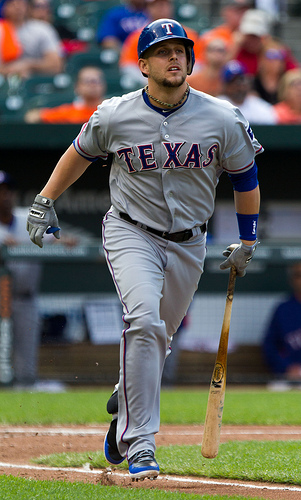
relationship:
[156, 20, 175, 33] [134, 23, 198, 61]
letter t on helmet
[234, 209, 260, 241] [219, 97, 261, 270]
sweat band on arm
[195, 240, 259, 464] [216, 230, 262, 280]
bat in hand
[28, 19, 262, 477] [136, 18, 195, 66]
man with hat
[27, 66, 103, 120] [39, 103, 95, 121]
man in shirt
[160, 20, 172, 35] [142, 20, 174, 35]
t on helmet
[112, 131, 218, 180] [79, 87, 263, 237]
texas on jersey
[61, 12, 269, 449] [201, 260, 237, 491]
baseball player holding bat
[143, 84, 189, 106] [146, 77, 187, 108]
necklace around neck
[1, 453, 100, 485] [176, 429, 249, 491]
line on ground